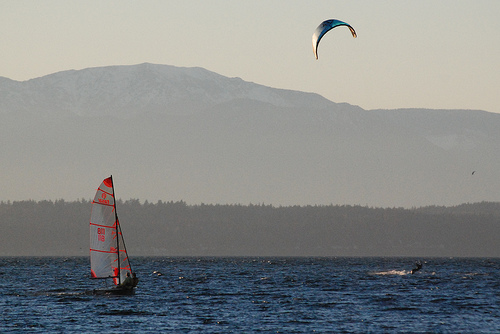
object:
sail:
[89, 175, 134, 285]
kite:
[312, 18, 358, 60]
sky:
[2, 2, 312, 62]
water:
[1, 295, 499, 333]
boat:
[94, 285, 138, 295]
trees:
[128, 194, 499, 258]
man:
[412, 261, 422, 275]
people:
[116, 272, 135, 289]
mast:
[111, 174, 121, 285]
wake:
[369, 269, 408, 276]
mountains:
[0, 62, 340, 133]